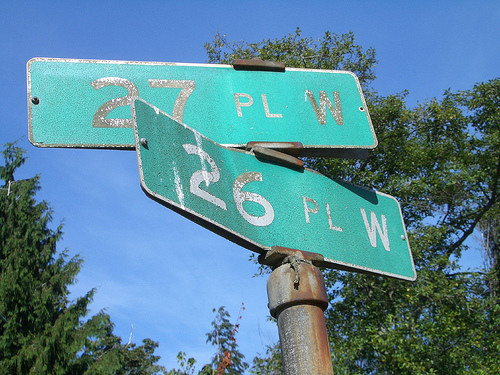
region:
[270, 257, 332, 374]
The pole the signs are mounted on.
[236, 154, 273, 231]
The number 6 on the street sign.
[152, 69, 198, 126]
The 7 on the street sign.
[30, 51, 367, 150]
The top street sign.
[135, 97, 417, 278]
The bottom sign on the pole.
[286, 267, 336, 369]
The rust stain on the pole.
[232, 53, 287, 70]
The metal tab on the top sign.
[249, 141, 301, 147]
The metal tab on the bottom of the top sign.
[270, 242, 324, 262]
The bottom metal tab on the bottom sign.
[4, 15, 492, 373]
The trees in the background.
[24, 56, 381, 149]
green street sign that says 27 place west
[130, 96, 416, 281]
green sign with silver trim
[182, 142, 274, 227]
number 26 in white reflective letters that are dirty and old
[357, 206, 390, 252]
large white 'W' that stands for west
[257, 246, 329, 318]
metal joint that connects metal to sign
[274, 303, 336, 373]
long, metal, rusty pipe holding road signs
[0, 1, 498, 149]
area of deep blue sky that is inhabited by clouds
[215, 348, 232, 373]
area of burnt and dried orange leaves that are dead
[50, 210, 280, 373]
area of sky that has faint white wispy clouds in it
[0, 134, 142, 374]
very tall and very dry pine tree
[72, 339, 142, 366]
Green leaves on a tree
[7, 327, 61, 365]
Green leaves on a tree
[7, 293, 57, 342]
Green leaves on a tree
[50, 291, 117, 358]
Green leaves on a tree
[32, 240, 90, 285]
Green leaves on a tree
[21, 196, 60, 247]
Green leaves on a tree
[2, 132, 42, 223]
Green leaves on a tree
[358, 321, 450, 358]
Green leaves on a tree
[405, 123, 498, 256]
Green leaves on a tree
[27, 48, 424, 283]
There are two signs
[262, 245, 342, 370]
The pole is rusty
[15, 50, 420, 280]
The signs are green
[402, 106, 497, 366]
The leaves are green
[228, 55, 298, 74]
The sign clips are rusty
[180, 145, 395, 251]
The lettering is white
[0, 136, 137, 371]
The trees are tall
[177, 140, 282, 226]
The sign has numbers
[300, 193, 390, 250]
The sign has letters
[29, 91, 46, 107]
The screws are grey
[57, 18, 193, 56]
The sky is clear and blue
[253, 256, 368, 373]
The pole to the sign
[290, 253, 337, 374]
The rust on the pole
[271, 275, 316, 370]
The color of the pole is gray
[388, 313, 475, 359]
The leaves on the tree are green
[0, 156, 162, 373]
The tree is tall with green leaves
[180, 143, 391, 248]
The sign is green and white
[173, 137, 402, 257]
The sign says "26 Pl W"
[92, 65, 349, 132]
The sign says " 27 Pl W"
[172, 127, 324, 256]
The sign in bent